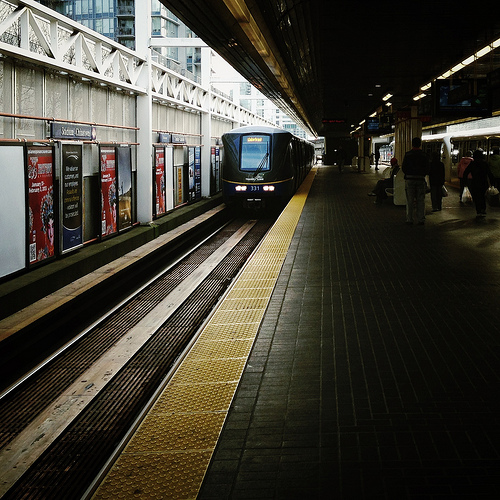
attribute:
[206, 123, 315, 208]
train — black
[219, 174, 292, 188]
stripe — yellow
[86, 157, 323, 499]
part — yellow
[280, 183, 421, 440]
platform — cement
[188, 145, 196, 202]
banner — promotional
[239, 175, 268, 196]
numbers — white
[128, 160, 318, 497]
yellow line — long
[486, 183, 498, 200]
bag — clear, plastic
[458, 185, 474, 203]
bag — clear, plastic